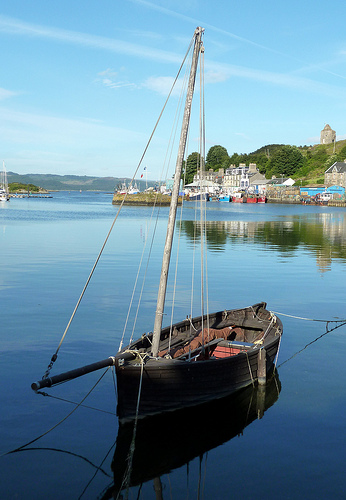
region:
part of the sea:
[274, 443, 286, 456]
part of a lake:
[122, 403, 136, 446]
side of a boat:
[175, 385, 183, 399]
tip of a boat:
[120, 395, 129, 406]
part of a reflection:
[162, 436, 170, 447]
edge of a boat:
[198, 365, 205, 379]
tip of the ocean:
[209, 324, 219, 350]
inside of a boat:
[167, 339, 183, 357]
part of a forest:
[259, 144, 269, 168]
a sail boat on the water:
[25, 250, 308, 439]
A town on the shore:
[148, 137, 340, 207]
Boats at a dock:
[105, 174, 174, 197]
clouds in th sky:
[10, 7, 306, 131]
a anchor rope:
[19, 376, 107, 452]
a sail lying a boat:
[164, 317, 237, 364]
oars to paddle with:
[174, 331, 225, 359]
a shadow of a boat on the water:
[95, 385, 280, 489]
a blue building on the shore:
[299, 182, 344, 201]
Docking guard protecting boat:
[254, 344, 268, 387]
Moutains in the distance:
[0, 160, 185, 205]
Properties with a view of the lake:
[183, 156, 345, 216]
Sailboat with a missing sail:
[27, 18, 286, 426]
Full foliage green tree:
[207, 140, 230, 168]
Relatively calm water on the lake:
[0, 206, 95, 255]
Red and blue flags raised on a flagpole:
[139, 164, 152, 188]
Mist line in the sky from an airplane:
[4, 13, 345, 93]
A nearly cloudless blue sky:
[2, 11, 345, 122]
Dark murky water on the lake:
[6, 402, 343, 492]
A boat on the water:
[84, 287, 302, 426]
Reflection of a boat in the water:
[23, 382, 343, 497]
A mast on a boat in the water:
[127, 25, 211, 356]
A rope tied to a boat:
[250, 283, 344, 340]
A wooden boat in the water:
[88, 288, 312, 437]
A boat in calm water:
[34, 221, 340, 480]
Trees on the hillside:
[182, 136, 343, 195]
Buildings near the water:
[183, 159, 297, 193]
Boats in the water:
[200, 190, 276, 205]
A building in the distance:
[313, 110, 338, 153]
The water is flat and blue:
[46, 212, 94, 269]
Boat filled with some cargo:
[176, 319, 251, 377]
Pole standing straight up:
[113, 108, 242, 290]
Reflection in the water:
[60, 416, 222, 495]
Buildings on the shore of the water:
[189, 146, 336, 220]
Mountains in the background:
[19, 159, 115, 187]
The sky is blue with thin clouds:
[30, 9, 144, 101]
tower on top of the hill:
[317, 105, 342, 142]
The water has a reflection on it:
[216, 202, 316, 273]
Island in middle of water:
[8, 175, 62, 216]